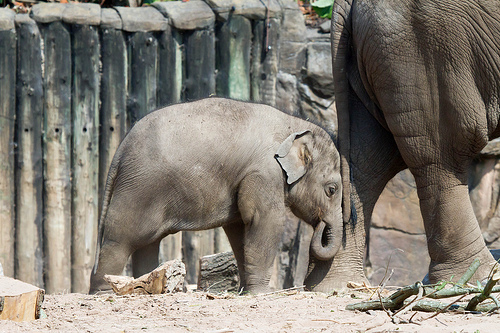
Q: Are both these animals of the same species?
A: Yes, all the animals are elephants.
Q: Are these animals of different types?
A: No, all the animals are elephants.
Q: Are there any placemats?
A: No, there are no placemats.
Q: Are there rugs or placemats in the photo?
A: No, there are no placemats or rugs.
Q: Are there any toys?
A: No, there are no toys.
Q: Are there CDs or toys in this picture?
A: No, there are no toys or cds.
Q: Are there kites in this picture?
A: No, there are no kites.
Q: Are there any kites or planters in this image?
A: No, there are no kites or planters.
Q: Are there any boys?
A: No, there are no boys.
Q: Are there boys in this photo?
A: No, there are no boys.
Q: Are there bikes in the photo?
A: No, there are no bikes.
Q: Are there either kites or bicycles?
A: No, there are no bicycles or kites.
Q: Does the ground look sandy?
A: Yes, the ground is sandy.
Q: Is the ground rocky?
A: No, the ground is sandy.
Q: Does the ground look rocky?
A: No, the ground is sandy.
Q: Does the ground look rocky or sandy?
A: The ground is sandy.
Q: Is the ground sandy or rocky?
A: The ground is sandy.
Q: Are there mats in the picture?
A: No, there are no mats.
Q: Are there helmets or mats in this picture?
A: No, there are no mats or helmets.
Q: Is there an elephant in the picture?
A: Yes, there is an elephant.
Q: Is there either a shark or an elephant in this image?
A: Yes, there is an elephant.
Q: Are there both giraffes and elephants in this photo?
A: No, there is an elephant but no giraffes.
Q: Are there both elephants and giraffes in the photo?
A: No, there is an elephant but no giraffes.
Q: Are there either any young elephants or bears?
A: Yes, there is a young elephant.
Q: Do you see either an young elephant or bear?
A: Yes, there is a young elephant.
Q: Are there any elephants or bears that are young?
A: Yes, the elephant is young.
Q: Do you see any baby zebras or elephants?
A: Yes, there is a baby elephant.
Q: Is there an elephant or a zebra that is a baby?
A: Yes, the elephant is a baby.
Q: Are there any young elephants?
A: Yes, there is a young elephant.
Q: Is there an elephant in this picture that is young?
A: Yes, there is an elephant that is young.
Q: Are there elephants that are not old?
A: Yes, there is an young elephant.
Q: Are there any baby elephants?
A: Yes, there is a baby elephant.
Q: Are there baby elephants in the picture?
A: Yes, there is a baby elephant.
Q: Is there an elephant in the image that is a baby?
A: Yes, there is an elephant that is a baby.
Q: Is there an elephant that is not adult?
A: Yes, there is an baby elephant.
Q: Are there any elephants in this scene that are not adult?
A: Yes, there is an baby elephant.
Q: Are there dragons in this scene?
A: No, there are no dragons.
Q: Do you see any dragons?
A: No, there are no dragons.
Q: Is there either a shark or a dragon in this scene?
A: No, there are no dragons or sharks.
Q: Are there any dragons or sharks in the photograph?
A: No, there are no dragons or sharks.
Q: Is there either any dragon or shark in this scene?
A: No, there are no dragons or sharks.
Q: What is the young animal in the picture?
A: The animal is an elephant.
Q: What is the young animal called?
A: The animal is an elephant.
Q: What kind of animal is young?
A: The animal is an elephant.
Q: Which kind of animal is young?
A: The animal is an elephant.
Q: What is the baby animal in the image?
A: The animal is an elephant.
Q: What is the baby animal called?
A: The animal is an elephant.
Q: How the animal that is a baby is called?
A: The animal is an elephant.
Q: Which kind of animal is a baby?
A: The animal is an elephant.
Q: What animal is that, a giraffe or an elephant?
A: That is an elephant.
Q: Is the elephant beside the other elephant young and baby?
A: Yes, the elephant is young and baby.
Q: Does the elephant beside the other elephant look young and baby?
A: Yes, the elephant is young and baby.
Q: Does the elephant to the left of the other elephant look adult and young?
A: No, the elephant is young but baby.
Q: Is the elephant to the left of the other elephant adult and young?
A: No, the elephant is young but baby.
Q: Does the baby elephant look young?
A: Yes, the elephant is young.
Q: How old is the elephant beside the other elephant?
A: The elephant is young.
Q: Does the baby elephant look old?
A: No, the elephant is young.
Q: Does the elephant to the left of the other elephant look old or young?
A: The elephant is young.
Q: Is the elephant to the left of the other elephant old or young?
A: The elephant is young.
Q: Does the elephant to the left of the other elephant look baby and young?
A: Yes, the elephant is a baby and young.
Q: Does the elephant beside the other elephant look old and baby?
A: No, the elephant is a baby but young.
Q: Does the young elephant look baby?
A: Yes, the elephant is a baby.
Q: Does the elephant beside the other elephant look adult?
A: No, the elephant is a baby.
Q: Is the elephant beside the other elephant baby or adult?
A: The elephant is a baby.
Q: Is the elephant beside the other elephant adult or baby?
A: The elephant is a baby.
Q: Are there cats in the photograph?
A: No, there are no cats.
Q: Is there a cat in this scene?
A: No, there are no cats.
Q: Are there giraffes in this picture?
A: No, there are no giraffes.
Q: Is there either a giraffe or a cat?
A: No, there are no giraffes or cats.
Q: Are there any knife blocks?
A: No, there are no knife blocks.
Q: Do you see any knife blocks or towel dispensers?
A: No, there are no knife blocks or towel dispensers.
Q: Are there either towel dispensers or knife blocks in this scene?
A: No, there are no knife blocks or towel dispensers.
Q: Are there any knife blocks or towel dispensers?
A: No, there are no knife blocks or towel dispensers.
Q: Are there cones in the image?
A: No, there are no cones.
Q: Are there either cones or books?
A: No, there are no cones or books.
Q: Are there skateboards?
A: No, there are no skateboards.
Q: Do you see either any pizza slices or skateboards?
A: No, there are no skateboards or pizza slices.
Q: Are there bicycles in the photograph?
A: No, there are no bicycles.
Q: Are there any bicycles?
A: No, there are no bicycles.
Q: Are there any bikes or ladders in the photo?
A: No, there are no bikes or ladders.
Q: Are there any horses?
A: No, there are no horses.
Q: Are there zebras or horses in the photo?
A: No, there are no horses or zebras.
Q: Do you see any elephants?
A: Yes, there is an elephant.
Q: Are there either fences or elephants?
A: Yes, there is an elephant.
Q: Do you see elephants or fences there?
A: Yes, there is an elephant.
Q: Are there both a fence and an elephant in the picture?
A: Yes, there are both an elephant and a fence.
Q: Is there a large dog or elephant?
A: Yes, there is a large elephant.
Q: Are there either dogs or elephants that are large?
A: Yes, the elephant is large.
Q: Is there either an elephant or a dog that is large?
A: Yes, the elephant is large.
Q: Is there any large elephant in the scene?
A: Yes, there is a large elephant.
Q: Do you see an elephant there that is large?
A: Yes, there is an elephant that is large.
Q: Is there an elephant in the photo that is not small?
A: Yes, there is a large elephant.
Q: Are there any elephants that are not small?
A: Yes, there is a large elephant.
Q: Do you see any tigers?
A: No, there are no tigers.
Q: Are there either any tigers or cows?
A: No, there are no tigers or cows.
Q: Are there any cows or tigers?
A: No, there are no tigers or cows.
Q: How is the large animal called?
A: The animal is an elephant.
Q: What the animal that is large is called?
A: The animal is an elephant.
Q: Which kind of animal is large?
A: The animal is an elephant.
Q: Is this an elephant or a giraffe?
A: This is an elephant.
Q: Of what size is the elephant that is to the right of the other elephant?
A: The elephant is large.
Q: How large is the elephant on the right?
A: The elephant is large.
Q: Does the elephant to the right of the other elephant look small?
A: No, the elephant is large.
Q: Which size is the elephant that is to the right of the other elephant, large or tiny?
A: The elephant is large.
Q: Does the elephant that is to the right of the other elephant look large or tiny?
A: The elephant is large.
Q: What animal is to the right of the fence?
A: The animal is an elephant.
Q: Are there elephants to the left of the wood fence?
A: No, the elephant is to the right of the fence.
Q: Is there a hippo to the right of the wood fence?
A: No, there is an elephant to the right of the fence.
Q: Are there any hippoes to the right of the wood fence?
A: No, there is an elephant to the right of the fence.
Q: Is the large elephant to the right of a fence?
A: Yes, the elephant is to the right of a fence.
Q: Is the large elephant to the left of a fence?
A: No, the elephant is to the right of a fence.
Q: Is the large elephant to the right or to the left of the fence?
A: The elephant is to the right of the fence.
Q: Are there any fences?
A: Yes, there is a fence.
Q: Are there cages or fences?
A: Yes, there is a fence.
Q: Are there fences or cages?
A: Yes, there is a fence.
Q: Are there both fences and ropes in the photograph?
A: No, there is a fence but no ropes.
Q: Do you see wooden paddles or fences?
A: Yes, there is a wood fence.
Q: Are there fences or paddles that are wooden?
A: Yes, the fence is wooden.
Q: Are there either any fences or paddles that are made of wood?
A: Yes, the fence is made of wood.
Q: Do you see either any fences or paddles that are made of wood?
A: Yes, the fence is made of wood.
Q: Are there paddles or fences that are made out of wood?
A: Yes, the fence is made of wood.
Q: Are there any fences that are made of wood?
A: Yes, there is a fence that is made of wood.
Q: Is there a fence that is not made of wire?
A: Yes, there is a fence that is made of wood.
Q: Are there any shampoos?
A: No, there are no shampoos.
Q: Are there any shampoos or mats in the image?
A: No, there are no shampoos or mats.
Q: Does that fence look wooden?
A: Yes, the fence is wooden.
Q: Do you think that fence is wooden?
A: Yes, the fence is wooden.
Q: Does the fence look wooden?
A: Yes, the fence is wooden.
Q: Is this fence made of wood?
A: Yes, the fence is made of wood.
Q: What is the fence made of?
A: The fence is made of wood.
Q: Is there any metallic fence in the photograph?
A: No, there is a fence but it is wooden.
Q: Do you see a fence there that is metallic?
A: No, there is a fence but it is wooden.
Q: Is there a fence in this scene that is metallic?
A: No, there is a fence but it is wooden.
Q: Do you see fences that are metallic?
A: No, there is a fence but it is wooden.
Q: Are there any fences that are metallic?
A: No, there is a fence but it is wooden.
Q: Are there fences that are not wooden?
A: No, there is a fence but it is wooden.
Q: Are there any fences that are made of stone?
A: No, there is a fence but it is made of wood.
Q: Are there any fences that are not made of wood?
A: No, there is a fence but it is made of wood.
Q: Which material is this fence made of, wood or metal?
A: The fence is made of wood.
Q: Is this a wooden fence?
A: Yes, this is a wooden fence.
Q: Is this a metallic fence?
A: No, this is a wooden fence.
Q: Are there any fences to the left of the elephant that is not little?
A: Yes, there is a fence to the left of the elephant.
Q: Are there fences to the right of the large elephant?
A: No, the fence is to the left of the elephant.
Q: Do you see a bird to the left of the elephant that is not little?
A: No, there is a fence to the left of the elephant.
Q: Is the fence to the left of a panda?
A: No, the fence is to the left of the elephant.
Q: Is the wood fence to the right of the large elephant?
A: No, the fence is to the left of the elephant.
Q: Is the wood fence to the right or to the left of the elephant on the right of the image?
A: The fence is to the left of the elephant.